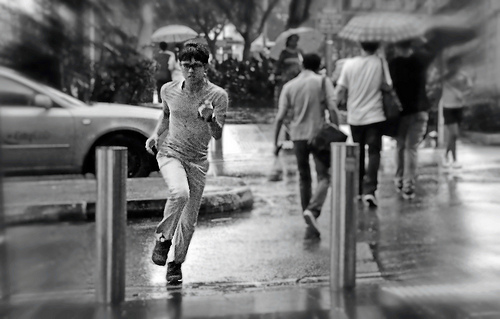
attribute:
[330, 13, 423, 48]
umbrella — checkered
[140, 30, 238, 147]
man — young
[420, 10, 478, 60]
umbrella — open 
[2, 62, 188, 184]
car — parked 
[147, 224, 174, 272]
tennis shoes — black 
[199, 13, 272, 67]
tree trunk — tall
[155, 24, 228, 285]
person — young , running 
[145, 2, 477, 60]
umbrellas — open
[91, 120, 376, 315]
poles — round , metal , up front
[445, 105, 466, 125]
shorts — dark 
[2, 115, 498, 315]
ground — wet 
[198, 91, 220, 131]
hand — fist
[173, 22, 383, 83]
hair — short, dark 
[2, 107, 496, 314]
road — wet